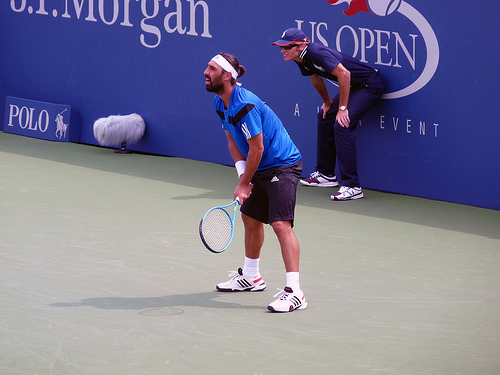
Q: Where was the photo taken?
A: At a tennis court.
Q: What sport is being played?
A: Tennis.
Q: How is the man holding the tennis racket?
A: With both hands.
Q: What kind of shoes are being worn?
A: Tennis shoes.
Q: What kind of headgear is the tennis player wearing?
A: A headband.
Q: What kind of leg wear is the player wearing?
A: Shorts.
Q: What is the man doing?
A: Playing tennis.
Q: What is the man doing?
A: Standing on a tennis court.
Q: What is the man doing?
A: Playing tennis.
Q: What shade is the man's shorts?
A: Black.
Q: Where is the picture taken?
A: Tennis court.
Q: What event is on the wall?
A: US OPEN.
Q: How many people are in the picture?
A: Two.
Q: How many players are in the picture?
A: One.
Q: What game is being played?
A: Tennis.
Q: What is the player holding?
A: A racket.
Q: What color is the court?
A: Green.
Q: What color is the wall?
A: Blue.